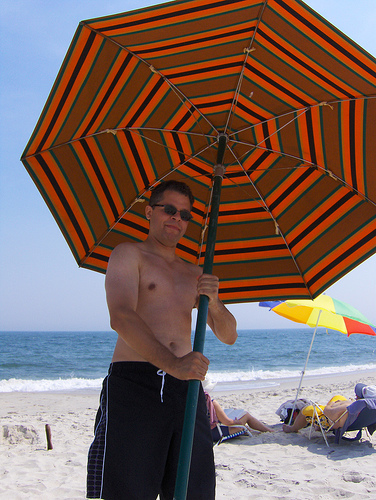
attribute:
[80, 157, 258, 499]
man — holding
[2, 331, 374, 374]
water — wavy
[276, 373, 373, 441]
person — sitting, reclining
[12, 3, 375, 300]
umbrella — striped, stuck, red, orange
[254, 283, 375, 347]
umbrella — colorful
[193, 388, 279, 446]
female — reading, laying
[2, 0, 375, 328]
sky — blue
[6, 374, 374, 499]
sand — marked